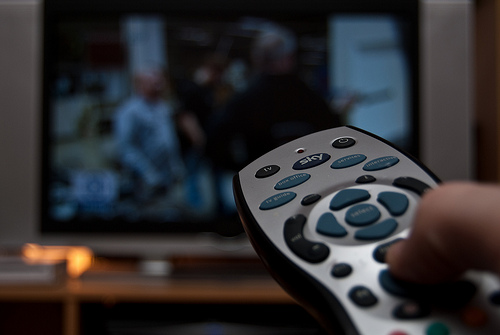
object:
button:
[345, 202, 381, 227]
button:
[273, 172, 307, 189]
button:
[328, 155, 368, 169]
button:
[360, 153, 396, 171]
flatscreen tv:
[5, 1, 476, 258]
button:
[293, 148, 329, 170]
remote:
[223, 109, 500, 335]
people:
[115, 23, 181, 202]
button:
[377, 262, 412, 301]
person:
[389, 178, 498, 330]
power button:
[331, 135, 358, 149]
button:
[392, 175, 431, 196]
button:
[355, 173, 375, 182]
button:
[300, 192, 321, 204]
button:
[333, 262, 352, 277]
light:
[65, 243, 94, 279]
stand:
[1, 245, 405, 333]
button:
[257, 190, 296, 210]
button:
[320, 212, 347, 234]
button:
[281, 211, 328, 264]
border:
[230, 124, 347, 172]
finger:
[390, 178, 498, 287]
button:
[373, 239, 409, 261]